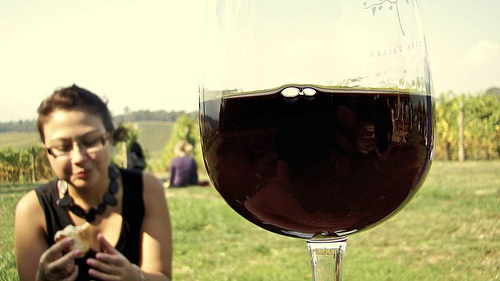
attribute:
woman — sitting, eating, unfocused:
[12, 84, 180, 281]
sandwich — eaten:
[53, 223, 105, 259]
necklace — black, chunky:
[56, 177, 126, 226]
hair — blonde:
[167, 140, 198, 191]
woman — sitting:
[162, 141, 200, 191]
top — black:
[31, 168, 151, 277]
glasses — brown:
[40, 130, 114, 159]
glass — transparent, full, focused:
[188, 41, 443, 281]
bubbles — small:
[281, 84, 321, 101]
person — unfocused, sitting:
[168, 137, 205, 188]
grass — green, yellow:
[16, 193, 487, 281]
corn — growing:
[0, 149, 47, 189]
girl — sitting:
[12, 86, 174, 280]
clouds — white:
[9, 30, 165, 93]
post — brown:
[454, 107, 469, 163]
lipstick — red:
[71, 170, 91, 180]